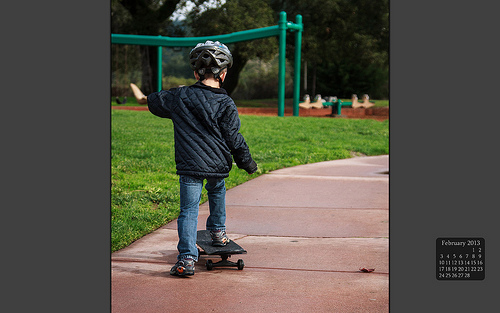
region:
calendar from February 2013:
[432, 233, 487, 284]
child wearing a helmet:
[173, 31, 232, 94]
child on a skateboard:
[115, 33, 290, 288]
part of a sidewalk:
[277, 183, 377, 286]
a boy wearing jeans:
[163, 159, 239, 276]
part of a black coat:
[119, 70, 214, 155]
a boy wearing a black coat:
[123, 34, 286, 185]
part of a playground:
[292, 80, 380, 117]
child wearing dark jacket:
[193, 114, 206, 137]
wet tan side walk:
[284, 214, 309, 226]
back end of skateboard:
[211, 245, 238, 257]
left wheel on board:
[203, 258, 219, 272]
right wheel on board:
[234, 258, 248, 273]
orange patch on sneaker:
[176, 266, 187, 274]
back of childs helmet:
[201, 54, 216, 74]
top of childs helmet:
[207, 39, 221, 47]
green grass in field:
[125, 156, 147, 178]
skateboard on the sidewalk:
[194, 228, 247, 272]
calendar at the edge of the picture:
[431, 228, 488, 286]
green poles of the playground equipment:
[276, 7, 305, 109]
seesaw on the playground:
[299, 91, 372, 112]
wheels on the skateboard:
[200, 257, 247, 274]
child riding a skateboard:
[125, 30, 261, 272]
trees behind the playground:
[301, 7, 369, 86]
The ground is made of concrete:
[286, 174, 391, 311]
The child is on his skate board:
[130, 27, 277, 279]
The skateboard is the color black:
[191, 215, 246, 274]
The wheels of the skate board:
[200, 255, 247, 275]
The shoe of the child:
[165, 249, 201, 282]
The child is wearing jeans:
[164, 170, 233, 262]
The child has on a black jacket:
[146, 84, 256, 179]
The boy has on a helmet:
[181, 35, 233, 86]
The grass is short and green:
[252, 113, 384, 168]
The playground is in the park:
[123, 15, 384, 305]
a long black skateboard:
[192, 222, 252, 274]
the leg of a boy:
[170, 162, 201, 253]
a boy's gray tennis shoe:
[165, 251, 197, 274]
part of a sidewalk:
[112, 155, 387, 312]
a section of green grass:
[241, 105, 381, 159]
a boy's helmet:
[190, 38, 237, 75]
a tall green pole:
[272, 10, 290, 112]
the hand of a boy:
[129, 81, 146, 103]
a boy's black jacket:
[142, 85, 255, 178]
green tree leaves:
[188, 0, 276, 34]